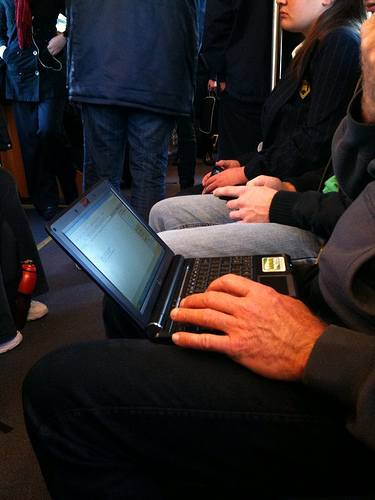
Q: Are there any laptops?
A: Yes, there is a laptop.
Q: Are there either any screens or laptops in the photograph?
A: Yes, there is a laptop.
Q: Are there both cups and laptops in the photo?
A: No, there is a laptop but no cups.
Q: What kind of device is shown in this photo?
A: The device is a laptop.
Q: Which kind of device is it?
A: The device is a laptop.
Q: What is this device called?
A: This is a laptop.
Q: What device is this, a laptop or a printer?
A: This is a laptop.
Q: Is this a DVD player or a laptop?
A: This is a laptop.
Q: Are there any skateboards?
A: No, there are no skateboards.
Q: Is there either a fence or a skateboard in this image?
A: No, there are no skateboards or fences.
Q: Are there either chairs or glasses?
A: No, there are no chairs or glasses.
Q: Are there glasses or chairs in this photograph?
A: No, there are no chairs or glasses.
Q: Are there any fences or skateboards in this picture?
A: No, there are no fences or skateboards.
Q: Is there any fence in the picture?
A: No, there are no fences.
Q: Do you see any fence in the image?
A: No, there are no fences.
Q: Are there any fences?
A: No, there are no fences.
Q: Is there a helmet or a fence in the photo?
A: No, there are no fences or helmets.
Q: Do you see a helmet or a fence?
A: No, there are no fences or helmets.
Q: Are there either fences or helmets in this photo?
A: No, there are no fences or helmets.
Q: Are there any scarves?
A: Yes, there is a scarf.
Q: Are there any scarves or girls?
A: Yes, there is a scarf.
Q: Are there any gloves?
A: No, there are no gloves.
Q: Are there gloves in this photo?
A: No, there are no gloves.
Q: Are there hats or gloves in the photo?
A: No, there are no gloves or hats.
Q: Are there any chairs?
A: No, there are no chairs.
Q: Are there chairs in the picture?
A: No, there are no chairs.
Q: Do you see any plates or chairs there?
A: No, there are no chairs or plates.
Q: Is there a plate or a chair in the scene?
A: No, there are no chairs or plates.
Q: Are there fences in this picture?
A: No, there are no fences.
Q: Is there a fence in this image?
A: No, there are no fences.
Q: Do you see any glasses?
A: No, there are no glasses.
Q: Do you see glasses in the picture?
A: No, there are no glasses.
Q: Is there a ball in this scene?
A: No, there are no balls.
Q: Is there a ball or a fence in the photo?
A: No, there are no balls or fences.